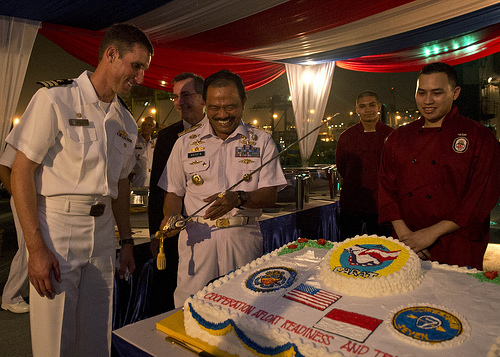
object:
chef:
[377, 62, 500, 271]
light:
[485, 76, 493, 85]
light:
[285, 94, 292, 101]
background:
[0, 0, 499, 164]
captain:
[3, 24, 152, 357]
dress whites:
[4, 70, 138, 356]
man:
[146, 73, 205, 320]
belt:
[182, 216, 256, 228]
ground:
[373, 177, 413, 215]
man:
[157, 69, 288, 309]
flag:
[282, 283, 342, 311]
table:
[111, 306, 206, 357]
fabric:
[40, 0, 499, 93]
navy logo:
[245, 266, 297, 294]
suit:
[147, 112, 207, 240]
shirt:
[4, 70, 138, 199]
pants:
[25, 205, 118, 357]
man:
[5, 23, 138, 356]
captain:
[156, 69, 287, 310]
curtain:
[283, 59, 336, 167]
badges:
[188, 141, 205, 165]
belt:
[36, 196, 111, 217]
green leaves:
[313, 153, 332, 166]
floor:
[266, 126, 327, 160]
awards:
[234, 138, 259, 164]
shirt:
[156, 119, 287, 219]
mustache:
[213, 116, 235, 121]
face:
[204, 84, 243, 134]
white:
[335, 326, 350, 335]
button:
[123, 143, 127, 148]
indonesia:
[204, 292, 398, 356]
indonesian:
[156, 119, 286, 309]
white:
[418, 283, 478, 303]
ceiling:
[0, 0, 499, 94]